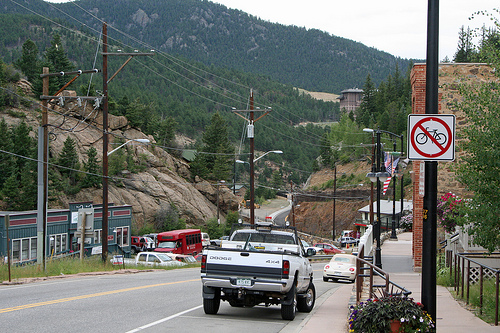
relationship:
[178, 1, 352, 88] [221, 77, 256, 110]
mountain and tree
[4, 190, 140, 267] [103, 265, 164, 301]
building by road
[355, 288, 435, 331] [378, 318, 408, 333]
flowers in pot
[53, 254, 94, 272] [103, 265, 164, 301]
grass by road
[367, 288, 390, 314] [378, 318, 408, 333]
flower in pot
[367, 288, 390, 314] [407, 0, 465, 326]
flower ear pole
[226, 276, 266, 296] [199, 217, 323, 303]
plate on truck